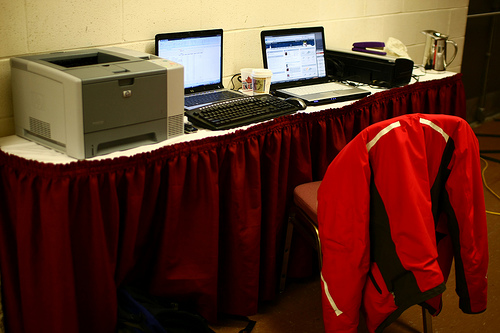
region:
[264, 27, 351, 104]
laptop on the table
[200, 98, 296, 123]
keyboard on the table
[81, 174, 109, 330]
pleat on the table cloth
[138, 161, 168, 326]
pleat on the table cloth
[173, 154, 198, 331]
pleat on the table cloth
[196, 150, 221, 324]
pleat on the table cloth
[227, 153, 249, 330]
pleat on the table cloth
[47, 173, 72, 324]
pleat on the table cloth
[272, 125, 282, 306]
pleat on the table cloth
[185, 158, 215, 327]
pleat on the table cloth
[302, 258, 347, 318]
white stripe on red jacket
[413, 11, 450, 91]
silver pitcher on right side of table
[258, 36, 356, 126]
black laptop on right side of table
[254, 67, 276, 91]
front white disposable cup on table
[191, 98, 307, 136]
black keyboard in front of laptop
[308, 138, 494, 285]
red and white jacket on back of a chair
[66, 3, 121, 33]
white brick wall in back of photo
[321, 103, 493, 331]
the jacket is red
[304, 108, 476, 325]
the jacket is red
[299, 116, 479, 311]
the jacket is red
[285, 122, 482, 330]
the jacket is red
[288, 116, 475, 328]
the jacket is red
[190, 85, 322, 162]
keyeboard on the table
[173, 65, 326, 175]
keyeboard on the table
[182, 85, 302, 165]
keyeboard on the table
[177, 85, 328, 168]
keyeboard on the table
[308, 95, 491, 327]
red jacket on chair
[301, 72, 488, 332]
red jacket on back of chair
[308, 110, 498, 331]
red windbreaker on chair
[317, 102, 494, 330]
red windbreaker on back of chair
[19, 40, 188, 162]
white and gray printer on table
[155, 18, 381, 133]
two laptops on table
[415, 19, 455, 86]
silver pitcher on side table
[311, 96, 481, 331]
white stripes on red jacket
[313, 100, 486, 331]
red jacket with white accents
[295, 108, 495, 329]
Red jacket on a chair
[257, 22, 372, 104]
Open laptop on a table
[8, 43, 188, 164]
Brown printer on a table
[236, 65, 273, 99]
Two styrofoam cups on a table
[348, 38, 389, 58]
Black stapler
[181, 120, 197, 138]
Computer mouse on a table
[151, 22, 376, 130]
Two open laptops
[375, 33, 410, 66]
Box of tissues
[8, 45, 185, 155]
a printer on a table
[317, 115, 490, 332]
a red coat draped over a chair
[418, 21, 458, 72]
a stainless steel water pitcher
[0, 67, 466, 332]
a red table skirt on a white table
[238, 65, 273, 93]
plastic cups on a table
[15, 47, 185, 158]
a printer on the desk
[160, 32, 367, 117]
two laptops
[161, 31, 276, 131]
a laptop on a desk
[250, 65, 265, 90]
a white cup on desk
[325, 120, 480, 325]
a red jacket on a chair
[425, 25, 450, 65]
a silver pitcher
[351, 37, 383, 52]
a black stapler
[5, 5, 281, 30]
white tile on the wall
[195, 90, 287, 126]
a black keyboard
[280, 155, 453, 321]
a red chair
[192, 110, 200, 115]
black key on the computer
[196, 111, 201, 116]
black key on the computer